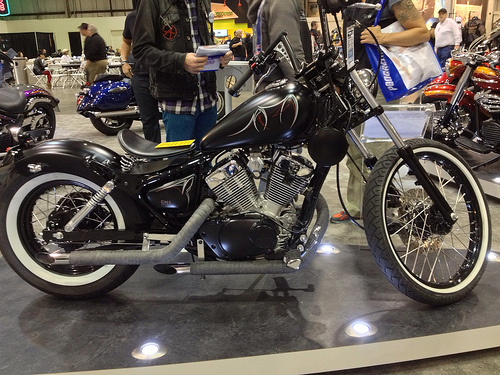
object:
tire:
[16, 99, 57, 145]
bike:
[0, 83, 60, 164]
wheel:
[0, 152, 149, 300]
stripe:
[5, 174, 126, 289]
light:
[343, 317, 377, 338]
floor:
[0, 70, 499, 372]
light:
[131, 340, 165, 361]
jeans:
[162, 106, 217, 142]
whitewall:
[360, 138, 492, 308]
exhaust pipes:
[34, 198, 217, 266]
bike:
[0, 3, 490, 305]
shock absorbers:
[63, 179, 117, 233]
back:
[0, 136, 158, 296]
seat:
[116, 125, 198, 159]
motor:
[207, 148, 315, 218]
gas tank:
[197, 80, 321, 149]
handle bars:
[227, 68, 257, 96]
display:
[33, 183, 328, 276]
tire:
[0, 160, 143, 298]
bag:
[362, 0, 446, 102]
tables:
[49, 53, 124, 87]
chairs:
[23, 54, 54, 90]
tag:
[153, 137, 195, 151]